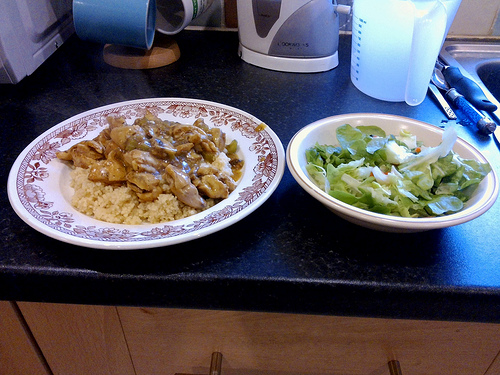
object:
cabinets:
[0, 301, 499, 374]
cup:
[345, 0, 464, 108]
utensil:
[424, 80, 458, 122]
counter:
[1, 26, 500, 325]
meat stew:
[54, 114, 238, 208]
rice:
[63, 166, 203, 225]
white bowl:
[285, 112, 499, 237]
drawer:
[113, 303, 498, 373]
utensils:
[431, 55, 498, 113]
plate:
[4, 100, 283, 253]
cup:
[68, 0, 157, 51]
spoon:
[425, 68, 495, 136]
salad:
[304, 123, 489, 219]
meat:
[164, 165, 208, 209]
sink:
[460, 61, 498, 107]